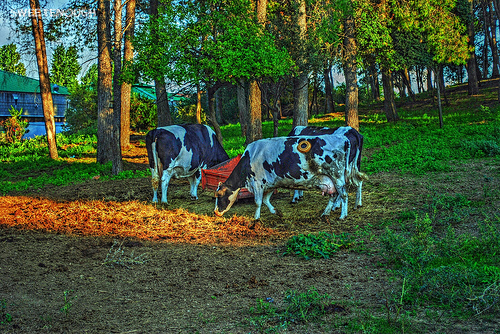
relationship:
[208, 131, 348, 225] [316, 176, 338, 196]
cow has udder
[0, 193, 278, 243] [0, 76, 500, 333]
light shining onto ground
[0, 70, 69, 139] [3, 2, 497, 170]
building in background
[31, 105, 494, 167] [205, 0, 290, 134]
grass under tree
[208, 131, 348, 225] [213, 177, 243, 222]
cow has head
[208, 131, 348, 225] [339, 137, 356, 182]
cow has tail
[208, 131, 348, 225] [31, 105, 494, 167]
cow chewing grass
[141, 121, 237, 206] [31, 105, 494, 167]
cow eating grass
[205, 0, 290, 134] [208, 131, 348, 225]
tree behind cow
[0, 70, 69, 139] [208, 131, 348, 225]
building near cow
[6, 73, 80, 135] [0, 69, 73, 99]
building has roof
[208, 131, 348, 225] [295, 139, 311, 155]
cow has object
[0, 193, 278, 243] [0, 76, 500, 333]
light shining on ground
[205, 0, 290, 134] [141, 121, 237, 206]
tree behind cow